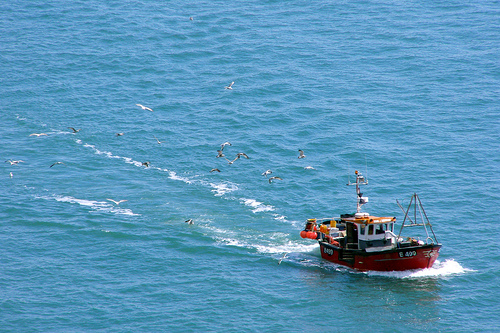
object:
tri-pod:
[393, 192, 441, 246]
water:
[2, 3, 494, 330]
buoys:
[182, 137, 354, 215]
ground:
[428, 137, 460, 160]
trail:
[0, 110, 305, 245]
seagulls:
[215, 211, 291, 257]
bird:
[137, 104, 153, 113]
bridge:
[340, 210, 395, 250]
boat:
[299, 169, 440, 274]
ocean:
[0, 0, 498, 332]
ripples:
[83, 139, 129, 161]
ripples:
[45, 184, 102, 208]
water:
[313, 2, 494, 205]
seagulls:
[209, 183, 296, 203]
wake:
[50, 127, 304, 261]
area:
[346, 170, 368, 186]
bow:
[420, 248, 438, 258]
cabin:
[340, 212, 398, 253]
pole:
[355, 166, 361, 213]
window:
[346, 222, 358, 248]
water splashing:
[372, 269, 466, 278]